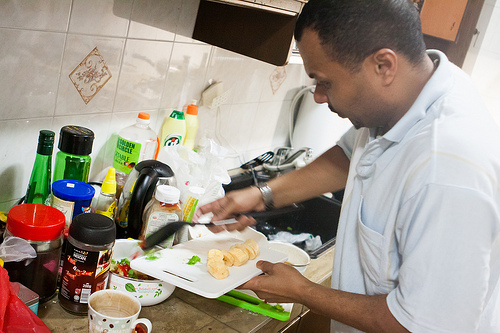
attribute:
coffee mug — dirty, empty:
[86, 286, 153, 331]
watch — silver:
[252, 173, 277, 212]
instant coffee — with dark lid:
[61, 210, 118, 317]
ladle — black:
[141, 210, 296, 255]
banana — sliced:
[199, 238, 268, 283]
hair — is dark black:
[287, 1, 432, 70]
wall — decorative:
[132, 40, 190, 93]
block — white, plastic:
[133, 225, 284, 306]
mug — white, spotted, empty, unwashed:
[86, 288, 153, 331]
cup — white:
[87, 288, 154, 330]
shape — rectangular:
[142, 227, 291, 297]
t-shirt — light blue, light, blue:
[333, 50, 493, 330]